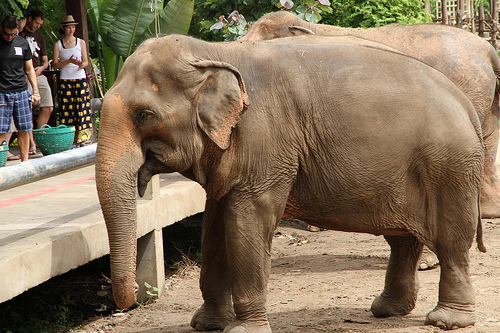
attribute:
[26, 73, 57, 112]
shorts — khaki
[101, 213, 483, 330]
dirt — brown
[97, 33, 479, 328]
elephant — big 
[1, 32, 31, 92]
t-shirt — black 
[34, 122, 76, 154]
basket — green 